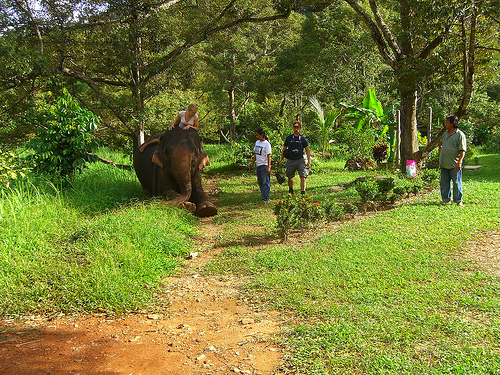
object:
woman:
[139, 106, 202, 159]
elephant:
[131, 124, 223, 221]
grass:
[0, 141, 500, 375]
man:
[436, 114, 471, 209]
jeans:
[438, 164, 465, 204]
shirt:
[435, 127, 470, 171]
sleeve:
[455, 132, 470, 154]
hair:
[444, 114, 460, 133]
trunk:
[159, 155, 195, 210]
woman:
[244, 126, 277, 205]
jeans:
[255, 164, 273, 201]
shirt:
[250, 139, 274, 170]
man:
[277, 119, 315, 202]